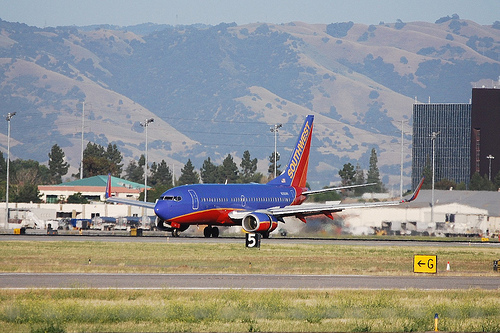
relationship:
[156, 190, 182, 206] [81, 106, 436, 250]
window on an airplane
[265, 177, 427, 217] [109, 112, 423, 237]
large wing on airplane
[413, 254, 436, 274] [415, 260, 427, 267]
sign has arrow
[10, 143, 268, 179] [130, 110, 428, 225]
trees behind airplane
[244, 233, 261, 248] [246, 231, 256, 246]
sign with number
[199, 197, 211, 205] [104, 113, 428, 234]
window on plane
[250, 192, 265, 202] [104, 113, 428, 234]
window on plane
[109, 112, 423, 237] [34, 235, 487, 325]
airplane sitting on ground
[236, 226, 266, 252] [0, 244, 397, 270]
sign on ground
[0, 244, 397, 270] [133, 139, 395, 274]
ground beside airplane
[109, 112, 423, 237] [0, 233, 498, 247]
airplane on runway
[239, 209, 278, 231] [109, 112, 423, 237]
engine on airplane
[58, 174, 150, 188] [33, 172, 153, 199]
roof on building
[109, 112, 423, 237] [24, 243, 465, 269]
airplane on ground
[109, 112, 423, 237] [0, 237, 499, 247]
airplane on ground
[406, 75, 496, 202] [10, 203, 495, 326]
buildings near airport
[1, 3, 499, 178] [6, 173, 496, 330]
hills behind airport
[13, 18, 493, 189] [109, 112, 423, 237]
mountain behind airplane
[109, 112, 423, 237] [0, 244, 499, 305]
airplane on ground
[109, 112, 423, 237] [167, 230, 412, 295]
airplane on ground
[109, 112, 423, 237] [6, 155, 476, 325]
airplane on ground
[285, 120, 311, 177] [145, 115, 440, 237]
name of airplane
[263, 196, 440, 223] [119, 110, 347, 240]
wings on airplane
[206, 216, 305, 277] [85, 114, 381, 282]
wheels on airplane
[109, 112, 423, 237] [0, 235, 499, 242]
airplane on runway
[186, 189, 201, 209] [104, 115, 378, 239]
door of an airplane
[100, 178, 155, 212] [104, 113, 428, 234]
large wing on a plane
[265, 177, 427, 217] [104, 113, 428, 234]
large wing on a plane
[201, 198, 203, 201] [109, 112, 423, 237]
window of a airplane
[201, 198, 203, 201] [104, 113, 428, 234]
window of a plane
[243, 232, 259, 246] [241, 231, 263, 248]
5 on sign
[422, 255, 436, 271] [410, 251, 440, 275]
g on sign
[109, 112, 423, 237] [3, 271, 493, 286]
airplane on runway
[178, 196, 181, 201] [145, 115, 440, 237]
window on airplane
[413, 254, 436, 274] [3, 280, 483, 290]
sign by runway